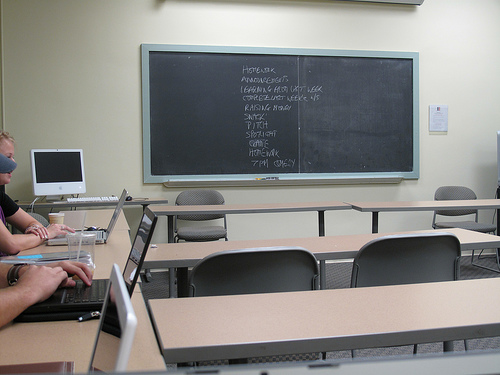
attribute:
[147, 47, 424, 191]
chalkboard — black, framed, large, full size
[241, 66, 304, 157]
writing — white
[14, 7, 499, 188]
wall — light beige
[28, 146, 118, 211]
computer — white, large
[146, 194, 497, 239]
table — long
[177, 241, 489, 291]
chairs — empty, metal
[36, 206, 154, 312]
computer — black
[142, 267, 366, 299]
floor — carpet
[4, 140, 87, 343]
people — sitting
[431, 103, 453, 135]
paper — white